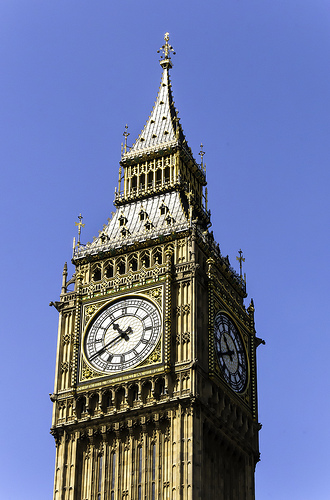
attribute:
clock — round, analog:
[78, 296, 160, 365]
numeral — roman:
[141, 308, 156, 320]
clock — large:
[210, 304, 252, 397]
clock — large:
[82, 296, 162, 374]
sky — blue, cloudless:
[237, 86, 281, 169]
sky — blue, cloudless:
[266, 382, 320, 483]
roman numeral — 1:
[132, 305, 140, 313]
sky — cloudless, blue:
[0, 0, 329, 499]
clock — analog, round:
[85, 283, 184, 364]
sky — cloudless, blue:
[0, 2, 328, 103]